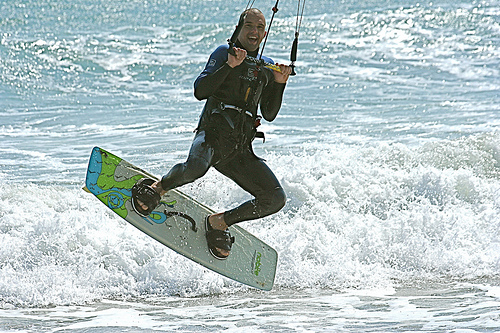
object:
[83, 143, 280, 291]
board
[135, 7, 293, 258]
man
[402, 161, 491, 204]
waves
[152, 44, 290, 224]
wetsuit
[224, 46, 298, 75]
handle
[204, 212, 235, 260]
feet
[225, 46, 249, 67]
hands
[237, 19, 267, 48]
smile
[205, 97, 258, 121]
safety straps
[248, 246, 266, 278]
brand name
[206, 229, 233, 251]
footstraps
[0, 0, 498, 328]
water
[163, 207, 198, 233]
handle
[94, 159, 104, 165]
decorations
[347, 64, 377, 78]
foam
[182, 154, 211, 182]
knees